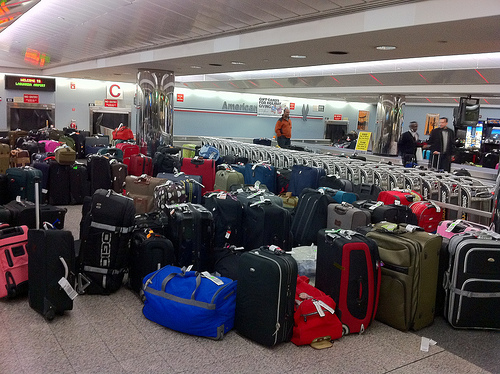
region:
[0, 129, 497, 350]
luggage waiting at an airport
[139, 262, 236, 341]
blue and gray duffel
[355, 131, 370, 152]
yellow sign sitting on top of carousel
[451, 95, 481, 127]
monitor hanging from ceiling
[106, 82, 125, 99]
white sign with a red letter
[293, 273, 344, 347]
large red duffel bag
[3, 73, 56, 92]
black rectangular wall sign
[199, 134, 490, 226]
row of silver luggage carts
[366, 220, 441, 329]
large olive green suitcase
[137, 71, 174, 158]
large silver support pole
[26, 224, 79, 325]
black luggage with a tag on it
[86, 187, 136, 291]
black luggage with a tag on it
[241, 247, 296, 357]
black luggage with a tag on it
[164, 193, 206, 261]
black luggage with a tag on it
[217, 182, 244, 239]
black luggage with a tag on it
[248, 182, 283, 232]
black luggage with a tag on it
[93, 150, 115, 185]
black luggage with a tag on it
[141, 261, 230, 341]
blue luggage with a tag on it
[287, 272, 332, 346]
red luggage with a tag on it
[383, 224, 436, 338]
brown luggage with a tag on it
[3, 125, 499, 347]
large group of luggage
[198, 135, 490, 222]
silver luggage racks in a row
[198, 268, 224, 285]
white luggage tag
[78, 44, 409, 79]
row of overhead lights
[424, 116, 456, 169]
man holding a luggage handle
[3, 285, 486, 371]
gray tiled floor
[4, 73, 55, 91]
electronic sign with orange and green writing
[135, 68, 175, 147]
shiny silver support column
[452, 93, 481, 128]
television set hanging from the ceiling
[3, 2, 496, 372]
luggage stacked at airport terminal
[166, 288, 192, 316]
the bag is blue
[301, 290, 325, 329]
the bag is laying down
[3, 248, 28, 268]
the bag is pink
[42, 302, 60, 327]
the bag has wheels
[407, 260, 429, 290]
the bag is olive green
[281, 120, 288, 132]
the coat is orange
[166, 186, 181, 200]
the bag has white dots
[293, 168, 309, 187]
the bag is dark blue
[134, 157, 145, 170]
the bag is maroon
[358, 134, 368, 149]
the sign is yellow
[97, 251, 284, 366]
a blue duffle bag on the floor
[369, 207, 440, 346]
a olive suitcase on the floor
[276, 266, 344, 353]
a red duffle bag on the floor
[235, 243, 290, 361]
a black suitcase on the floor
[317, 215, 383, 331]
a red and black suitcase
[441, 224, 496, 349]
a black and gray suitcase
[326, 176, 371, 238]
a gray suitcase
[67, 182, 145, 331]
a black duffle bag on the floor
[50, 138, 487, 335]
suitcases on the floor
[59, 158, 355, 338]
duffle bags on the floor